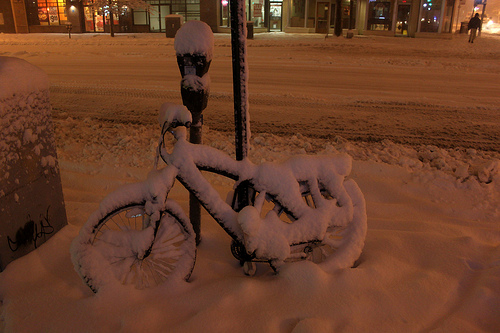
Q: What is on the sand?
A: Cycle.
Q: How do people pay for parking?
A: The meter.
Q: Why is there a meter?
A: Collect money for parking.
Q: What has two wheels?
A: Bike.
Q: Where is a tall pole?
A: Right of meter.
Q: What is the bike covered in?
A: Snow.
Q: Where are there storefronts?
A: Background.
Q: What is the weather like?
A: Cold.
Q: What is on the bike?
A: Snow.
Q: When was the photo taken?
A: Night.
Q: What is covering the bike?
A: Snow.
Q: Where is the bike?
A: Against the pole.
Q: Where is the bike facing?
A: Left.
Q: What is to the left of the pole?
A: Parking meter.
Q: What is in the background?
A: Shop fronts.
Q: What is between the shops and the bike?
A: Street.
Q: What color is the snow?
A: White.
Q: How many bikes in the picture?
A: 1.